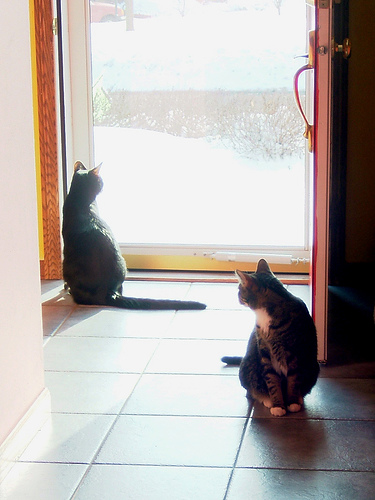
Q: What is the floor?
A: Tiled.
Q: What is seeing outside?
A: The black cat.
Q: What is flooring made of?
A: Tile.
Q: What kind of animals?
A: Cats.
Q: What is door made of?
A: Wood.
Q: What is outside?
A: Snow.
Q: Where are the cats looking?
A: Outside the door.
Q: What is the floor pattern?
A: Tile.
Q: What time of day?
A: Bright.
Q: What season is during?
A: Snow.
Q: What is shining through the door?
A: Light.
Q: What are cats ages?
A: Adult.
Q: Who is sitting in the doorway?
A: A cat.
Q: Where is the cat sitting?
A: In the doorway.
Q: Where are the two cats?
A: On the floor.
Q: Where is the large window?
A: In the door.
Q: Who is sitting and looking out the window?
A: One cat.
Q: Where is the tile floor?
A: Under the cats.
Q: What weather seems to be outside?
A: Snow.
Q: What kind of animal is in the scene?
A: Cats.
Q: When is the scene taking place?
A: Daytime.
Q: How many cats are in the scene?
A: Two.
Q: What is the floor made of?
A: Tiles.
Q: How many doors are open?
A: One.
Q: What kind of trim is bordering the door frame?
A: Wood.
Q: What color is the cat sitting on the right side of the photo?
A: White, grey and black.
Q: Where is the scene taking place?
A: At a front door.